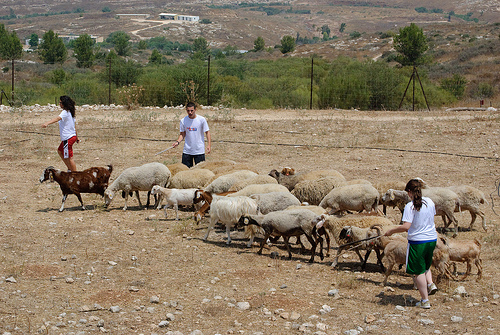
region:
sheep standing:
[115, 164, 357, 241]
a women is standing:
[397, 183, 442, 304]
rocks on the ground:
[221, 291, 353, 333]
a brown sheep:
[37, 164, 109, 199]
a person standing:
[44, 95, 89, 170]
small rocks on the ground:
[120, 282, 180, 330]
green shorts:
[407, 243, 432, 271]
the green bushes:
[222, 60, 287, 104]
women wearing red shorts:
[60, 139, 76, 155]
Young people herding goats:
[30, 91, 490, 326]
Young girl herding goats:
[330, 175, 445, 310]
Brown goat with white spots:
[35, 160, 112, 217]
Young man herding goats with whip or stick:
[152, 101, 210, 179]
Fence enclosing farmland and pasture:
[2, 46, 497, 113]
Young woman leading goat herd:
[30, 95, 113, 216]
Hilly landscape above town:
[1, 19, 498, 91]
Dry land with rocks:
[13, 243, 181, 334]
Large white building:
[117, 7, 211, 48]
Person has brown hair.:
[405, 178, 419, 199]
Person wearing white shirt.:
[405, 195, 443, 244]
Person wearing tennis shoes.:
[413, 275, 437, 320]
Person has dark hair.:
[181, 93, 203, 125]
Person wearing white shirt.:
[186, 117, 217, 153]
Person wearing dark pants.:
[178, 145, 209, 176]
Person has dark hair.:
[56, 90, 90, 125]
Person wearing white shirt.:
[51, 116, 82, 136]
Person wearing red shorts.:
[35, 145, 85, 172]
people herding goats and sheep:
[36, 93, 498, 315]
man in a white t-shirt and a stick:
[152, 103, 214, 165]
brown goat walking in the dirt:
[35, 163, 112, 212]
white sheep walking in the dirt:
[105, 161, 488, 280]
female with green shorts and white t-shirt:
[389, 180, 444, 312]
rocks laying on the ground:
[1, 261, 498, 333]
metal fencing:
[1, 46, 498, 108]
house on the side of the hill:
[156, 8, 202, 26]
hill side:
[291, 0, 498, 85]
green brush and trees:
[1, 23, 499, 116]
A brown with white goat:
[30, 169, 120, 206]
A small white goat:
[142, 179, 194, 216]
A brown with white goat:
[195, 187, 233, 207]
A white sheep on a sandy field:
[97, 173, 171, 194]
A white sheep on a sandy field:
[237, 213, 317, 255]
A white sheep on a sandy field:
[320, 187, 392, 217]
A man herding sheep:
[172, 89, 217, 181]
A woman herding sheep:
[402, 171, 444, 303]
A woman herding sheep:
[46, 79, 85, 169]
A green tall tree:
[391, 30, 428, 112]